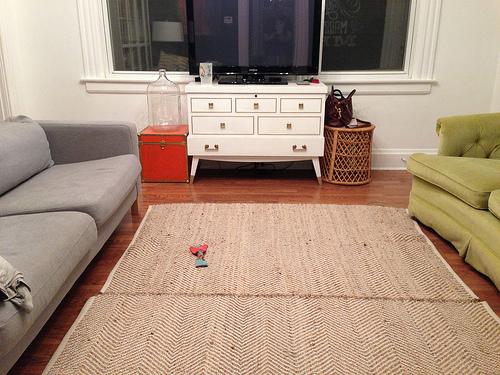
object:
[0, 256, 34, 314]
clothing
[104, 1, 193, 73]
window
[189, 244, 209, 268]
toy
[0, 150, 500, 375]
ground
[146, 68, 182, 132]
bottle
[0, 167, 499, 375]
floor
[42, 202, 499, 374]
area rug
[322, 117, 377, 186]
basket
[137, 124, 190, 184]
chest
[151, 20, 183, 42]
lamp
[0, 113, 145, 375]
couch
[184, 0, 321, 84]
tv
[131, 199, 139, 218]
leg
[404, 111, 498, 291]
couch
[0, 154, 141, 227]
cushion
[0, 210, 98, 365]
cushion